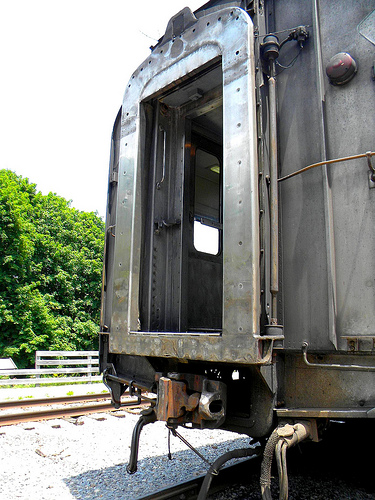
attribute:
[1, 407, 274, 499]
pebbles — white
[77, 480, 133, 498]
rocks — white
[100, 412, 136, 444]
pebbles — white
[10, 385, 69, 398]
pebbles — white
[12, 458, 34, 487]
pebbles — white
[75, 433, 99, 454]
pebbles — white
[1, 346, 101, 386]
fence — wood, white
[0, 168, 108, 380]
trees — green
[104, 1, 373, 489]
train — silver, grey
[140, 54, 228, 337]
door — open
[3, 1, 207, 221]
sky — white, bright, cloudy